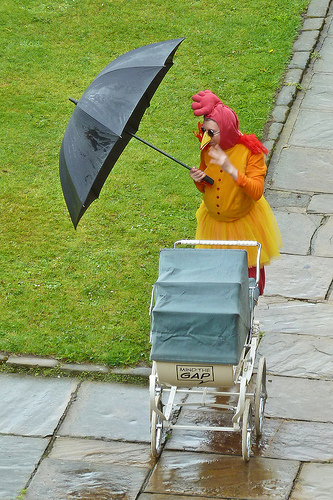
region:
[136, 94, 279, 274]
a lady holding an umbrella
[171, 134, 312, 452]
lady is standing beside a trolley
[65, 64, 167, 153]
umbrella is black in color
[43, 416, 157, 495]
the pavements are wet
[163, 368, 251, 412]
trolley is white in color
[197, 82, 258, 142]
head is covered with ared scarf mavin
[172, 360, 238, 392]
worss are written in black color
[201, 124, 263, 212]
lady is wearing sungalsses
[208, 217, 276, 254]
the skie=rt is yellow in color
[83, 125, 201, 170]
Person holding umbrella.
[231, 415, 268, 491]
Gray tire on stroller.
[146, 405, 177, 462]
Gray tire on baby stroller.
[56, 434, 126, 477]
Ground is wet and shiny.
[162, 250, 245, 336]
Blueish gray cover on baby stroller.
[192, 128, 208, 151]
Person wearing beak on face.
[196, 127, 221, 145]
Sunglasses on person's face.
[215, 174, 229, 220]
Red buttons on person's shirt.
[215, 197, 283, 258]
Person wearing yellow dress.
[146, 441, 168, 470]
part of a metal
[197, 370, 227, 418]
part of a chaor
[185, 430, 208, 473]
par tf a line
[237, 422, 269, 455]
Gray tire on baby carriage.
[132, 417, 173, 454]
Gray tire on baby carriage.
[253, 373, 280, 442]
Gray tire on baby carriage.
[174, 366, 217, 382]
Black writing on white sticker.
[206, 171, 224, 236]
Red buttons on person's dress.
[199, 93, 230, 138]
Person dressed like a chicken.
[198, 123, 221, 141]
Sunglasses on person's face.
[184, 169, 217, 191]
Handle on umbrella is black.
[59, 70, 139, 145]
Umbrella is black in color.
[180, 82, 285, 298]
person wearing a costume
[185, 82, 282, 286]
person wearing a costume of rooster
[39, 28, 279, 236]
person holding an umbrella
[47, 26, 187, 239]
a black umbrella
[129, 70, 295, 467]
person in front a stroller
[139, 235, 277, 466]
the stroller's roof is blue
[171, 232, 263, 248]
handle of stroller is white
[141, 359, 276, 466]
wheels of stroller are big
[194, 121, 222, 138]
sunglasses on face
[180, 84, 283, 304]
costume is red and yellow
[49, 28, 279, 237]
A person holding an umbrella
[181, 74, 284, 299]
A person wearing a rooster costume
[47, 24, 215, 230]
An open black umbrella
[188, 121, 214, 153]
A yellow bird beak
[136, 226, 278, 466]
A blue and white baby carriage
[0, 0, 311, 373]
Green grass is on the ground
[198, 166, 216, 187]
Black handle of an umbrella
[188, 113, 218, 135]
A pair of sunglasses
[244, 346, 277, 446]
A round white wheel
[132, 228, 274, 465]
the baby carriage is blue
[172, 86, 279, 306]
a woman is wearing a chicken costume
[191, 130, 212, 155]
the beak is yellow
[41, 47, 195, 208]
the umbrella is black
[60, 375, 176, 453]
the square is stone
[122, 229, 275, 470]
the carriage is cream and blue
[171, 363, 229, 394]
the sign has black letters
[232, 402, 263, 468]
the wheel is small